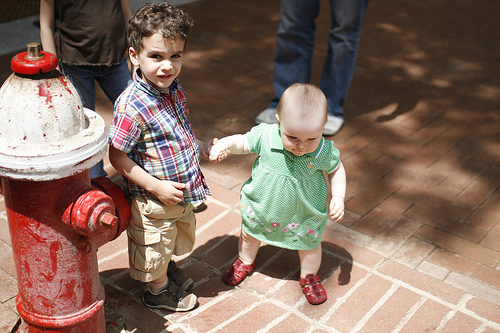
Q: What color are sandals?
A: Red.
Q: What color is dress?
A: Green.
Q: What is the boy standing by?
A: Hydrant.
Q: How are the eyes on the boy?
A: Open.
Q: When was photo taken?
A: Daytime.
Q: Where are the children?
A: On sidewalk.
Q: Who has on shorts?
A: The boy.